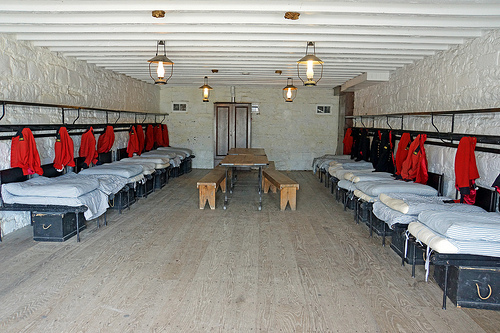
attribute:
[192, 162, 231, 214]
bench — brown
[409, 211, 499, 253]
pillow — white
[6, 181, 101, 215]
pillow — white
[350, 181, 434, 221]
pillow — white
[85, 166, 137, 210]
pillow — white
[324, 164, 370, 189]
pillow — white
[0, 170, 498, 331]
floor — polished , wooden 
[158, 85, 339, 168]
stone walls — white, hewn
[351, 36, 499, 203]
stone walls — white, hewn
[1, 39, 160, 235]
stone walls — white, hewn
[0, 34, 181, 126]
wall — textured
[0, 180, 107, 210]
mattress — folded 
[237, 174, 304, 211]
bench — brown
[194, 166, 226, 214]
bench — wooden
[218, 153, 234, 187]
bench — wooden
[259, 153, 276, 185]
bench — wooden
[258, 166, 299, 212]
bench — wooden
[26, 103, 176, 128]
hanger — long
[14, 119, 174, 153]
clothes — red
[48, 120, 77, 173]
fabric — red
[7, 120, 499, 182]
robes — red, hanging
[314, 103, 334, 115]
vent — high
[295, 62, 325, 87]
light — on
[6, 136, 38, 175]
robe — red, hanging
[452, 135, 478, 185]
robe — red, hanging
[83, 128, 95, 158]
robe — red, hanging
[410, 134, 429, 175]
robe — red, hanging